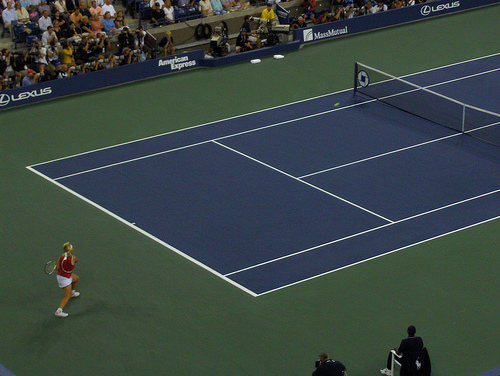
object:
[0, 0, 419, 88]
person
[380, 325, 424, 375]
man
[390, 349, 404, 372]
chair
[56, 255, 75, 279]
shirt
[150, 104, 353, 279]
line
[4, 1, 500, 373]
trim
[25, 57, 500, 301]
match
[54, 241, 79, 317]
lady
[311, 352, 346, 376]
person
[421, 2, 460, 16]
logo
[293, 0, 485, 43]
wall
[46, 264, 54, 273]
net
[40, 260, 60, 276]
racket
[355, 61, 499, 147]
net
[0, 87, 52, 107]
word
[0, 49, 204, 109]
wall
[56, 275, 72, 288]
skirt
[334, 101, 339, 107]
ball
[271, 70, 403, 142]
air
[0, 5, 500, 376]
court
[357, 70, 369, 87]
logo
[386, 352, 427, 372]
white stand